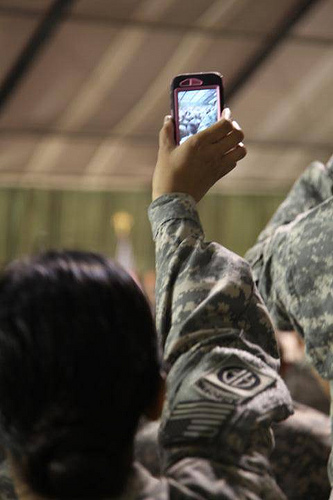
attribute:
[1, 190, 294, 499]
army uniform — camouflage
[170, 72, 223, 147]
cellphone — black, pink, up, used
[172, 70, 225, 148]
case — black, pink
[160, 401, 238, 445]
american flag — blurry, patch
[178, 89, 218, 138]
screen — on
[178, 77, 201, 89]
speaker — pink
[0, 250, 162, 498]
hair — wrapped, dark, brown, black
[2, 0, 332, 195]
ceiling — light colored, white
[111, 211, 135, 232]
tip — yellow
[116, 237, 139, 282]
flag — blurry, white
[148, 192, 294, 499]
sleeve — camouflage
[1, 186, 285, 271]
wall — green